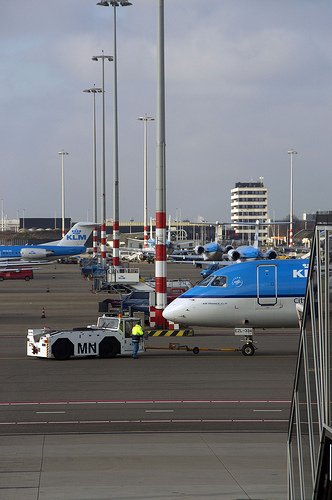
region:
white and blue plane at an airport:
[0, 222, 99, 265]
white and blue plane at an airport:
[162, 256, 331, 332]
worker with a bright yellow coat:
[130, 321, 144, 359]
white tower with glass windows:
[230, 181, 270, 243]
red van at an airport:
[0, 265, 33, 280]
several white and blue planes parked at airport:
[123, 218, 291, 263]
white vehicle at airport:
[25, 315, 143, 361]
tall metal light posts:
[82, 0, 166, 331]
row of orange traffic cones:
[40, 263, 57, 321]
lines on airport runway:
[3, 399, 320, 423]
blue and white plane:
[162, 260, 309, 325]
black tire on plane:
[243, 343, 255, 356]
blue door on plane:
[257, 266, 276, 306]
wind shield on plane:
[200, 274, 214, 286]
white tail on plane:
[59, 221, 102, 248]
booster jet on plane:
[227, 248, 239, 260]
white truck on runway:
[26, 315, 145, 359]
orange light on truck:
[117, 313, 121, 317]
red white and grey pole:
[155, 0, 167, 323]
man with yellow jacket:
[131, 321, 143, 355]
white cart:
[18, 296, 150, 365]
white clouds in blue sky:
[175, 18, 219, 54]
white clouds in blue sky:
[248, 56, 284, 102]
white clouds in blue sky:
[202, 61, 237, 112]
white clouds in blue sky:
[186, 101, 218, 156]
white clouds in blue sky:
[18, 22, 54, 56]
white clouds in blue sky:
[12, 68, 50, 102]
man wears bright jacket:
[129, 320, 142, 358]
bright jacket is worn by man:
[129, 321, 144, 339]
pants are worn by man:
[130, 339, 138, 357]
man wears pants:
[128, 322, 141, 356]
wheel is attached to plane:
[240, 341, 254, 356]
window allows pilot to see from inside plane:
[198, 274, 228, 286]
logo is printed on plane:
[64, 228, 87, 243]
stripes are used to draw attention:
[146, 329, 193, 336]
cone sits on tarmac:
[38, 304, 46, 319]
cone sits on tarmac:
[44, 283, 51, 294]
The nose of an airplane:
[157, 250, 242, 333]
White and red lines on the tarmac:
[0, 391, 291, 427]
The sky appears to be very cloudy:
[0, 0, 327, 219]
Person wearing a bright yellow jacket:
[126, 316, 148, 339]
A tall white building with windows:
[222, 173, 270, 242]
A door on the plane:
[249, 256, 281, 309]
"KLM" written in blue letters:
[58, 226, 87, 243]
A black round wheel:
[237, 338, 259, 362]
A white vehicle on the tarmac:
[17, 305, 146, 363]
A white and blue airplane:
[0, 216, 101, 268]